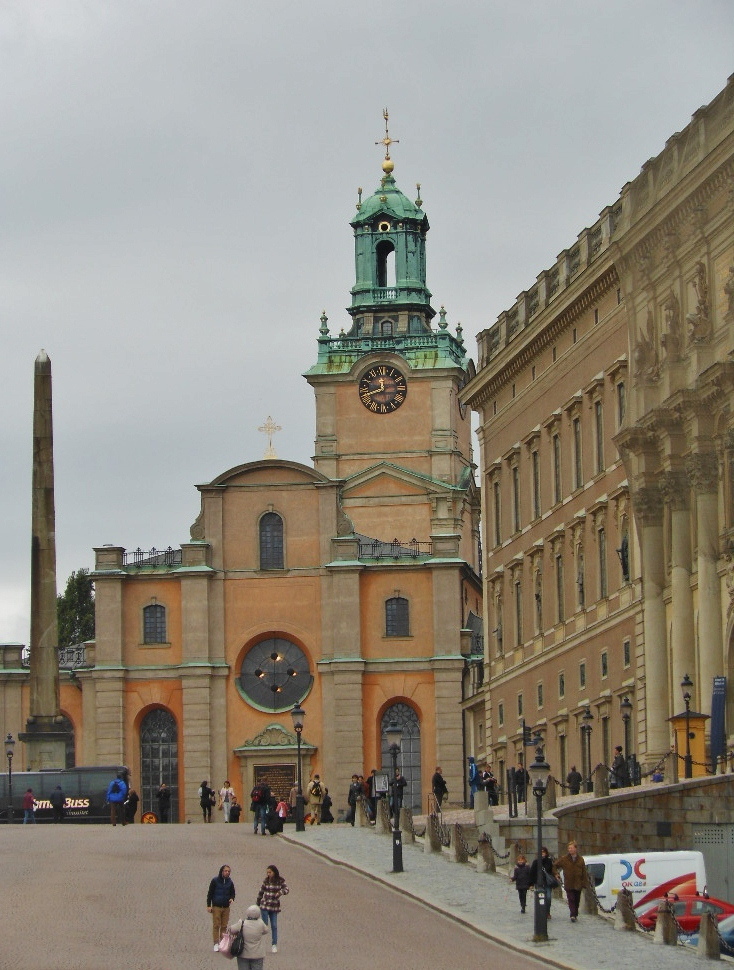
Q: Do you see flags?
A: No, there are no flags.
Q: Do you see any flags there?
A: No, there are no flags.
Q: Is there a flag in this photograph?
A: No, there are no flags.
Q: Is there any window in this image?
A: Yes, there is a window.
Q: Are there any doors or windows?
A: Yes, there is a window.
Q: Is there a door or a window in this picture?
A: Yes, there is a window.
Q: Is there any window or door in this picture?
A: Yes, there is a window.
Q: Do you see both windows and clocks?
A: Yes, there are both a window and a clock.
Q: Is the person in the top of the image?
A: No, the person is in the bottom of the image.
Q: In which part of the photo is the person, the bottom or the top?
A: The person is in the bottom of the image.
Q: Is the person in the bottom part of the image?
A: Yes, the person is in the bottom of the image.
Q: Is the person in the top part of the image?
A: No, the person is in the bottom of the image.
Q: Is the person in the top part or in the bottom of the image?
A: The person is in the bottom of the image.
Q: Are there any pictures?
A: No, there are no pictures.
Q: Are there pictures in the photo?
A: No, there are no pictures.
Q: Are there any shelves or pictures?
A: No, there are no pictures or shelves.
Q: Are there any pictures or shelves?
A: No, there are no pictures or shelves.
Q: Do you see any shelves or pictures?
A: No, there are no pictures or shelves.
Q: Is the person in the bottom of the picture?
A: Yes, the person is in the bottom of the image.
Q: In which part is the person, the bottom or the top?
A: The person is in the bottom of the image.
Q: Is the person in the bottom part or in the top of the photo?
A: The person is in the bottom of the image.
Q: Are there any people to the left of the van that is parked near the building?
A: Yes, there is a person to the left of the van.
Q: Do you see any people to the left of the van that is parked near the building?
A: Yes, there is a person to the left of the van.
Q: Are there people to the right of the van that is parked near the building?
A: No, the person is to the left of the van.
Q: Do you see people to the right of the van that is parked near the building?
A: No, the person is to the left of the van.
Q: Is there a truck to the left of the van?
A: No, there is a person to the left of the van.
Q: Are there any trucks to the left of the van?
A: No, there is a person to the left of the van.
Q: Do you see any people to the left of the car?
A: Yes, there is a person to the left of the car.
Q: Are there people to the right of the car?
A: No, the person is to the left of the car.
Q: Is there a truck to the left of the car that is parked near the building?
A: No, there is a person to the left of the car.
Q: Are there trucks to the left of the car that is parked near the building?
A: No, there is a person to the left of the car.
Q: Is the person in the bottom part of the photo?
A: Yes, the person is in the bottom of the image.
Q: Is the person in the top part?
A: No, the person is in the bottom of the image.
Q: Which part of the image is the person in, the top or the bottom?
A: The person is in the bottom of the image.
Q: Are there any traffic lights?
A: No, there are no traffic lights.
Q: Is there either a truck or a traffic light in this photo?
A: No, there are no traffic lights or trucks.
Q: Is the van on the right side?
A: Yes, the van is on the right of the image.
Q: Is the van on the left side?
A: No, the van is on the right of the image.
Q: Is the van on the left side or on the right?
A: The van is on the right of the image.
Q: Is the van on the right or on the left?
A: The van is on the right of the image.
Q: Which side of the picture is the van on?
A: The van is on the right of the image.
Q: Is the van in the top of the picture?
A: No, the van is in the bottom of the image.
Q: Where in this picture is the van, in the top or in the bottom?
A: The van is in the bottom of the image.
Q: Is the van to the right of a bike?
A: No, the van is to the right of a person.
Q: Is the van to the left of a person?
A: No, the van is to the right of a person.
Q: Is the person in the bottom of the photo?
A: Yes, the person is in the bottom of the image.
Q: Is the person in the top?
A: No, the person is in the bottom of the image.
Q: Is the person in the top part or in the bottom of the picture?
A: The person is in the bottom of the image.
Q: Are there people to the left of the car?
A: Yes, there is a person to the left of the car.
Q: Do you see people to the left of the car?
A: Yes, there is a person to the left of the car.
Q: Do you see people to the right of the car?
A: No, the person is to the left of the car.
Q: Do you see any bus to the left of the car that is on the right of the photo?
A: No, there is a person to the left of the car.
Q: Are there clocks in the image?
A: Yes, there is a clock.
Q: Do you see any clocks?
A: Yes, there is a clock.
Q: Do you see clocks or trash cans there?
A: Yes, there is a clock.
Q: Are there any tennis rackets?
A: No, there are no tennis rackets.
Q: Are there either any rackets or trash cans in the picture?
A: No, there are no rackets or trash cans.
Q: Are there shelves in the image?
A: No, there are no shelves.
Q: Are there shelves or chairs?
A: No, there are no shelves or chairs.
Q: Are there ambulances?
A: No, there are no ambulances.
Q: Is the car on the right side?
A: Yes, the car is on the right of the image.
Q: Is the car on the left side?
A: No, the car is on the right of the image.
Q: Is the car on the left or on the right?
A: The car is on the right of the image.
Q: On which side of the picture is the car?
A: The car is on the right of the image.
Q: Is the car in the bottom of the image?
A: Yes, the car is in the bottom of the image.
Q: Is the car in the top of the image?
A: No, the car is in the bottom of the image.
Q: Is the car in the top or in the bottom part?
A: The car is in the bottom of the image.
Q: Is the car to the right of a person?
A: Yes, the car is to the right of a person.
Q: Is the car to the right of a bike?
A: No, the car is to the right of a person.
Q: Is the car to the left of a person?
A: No, the car is to the right of a person.